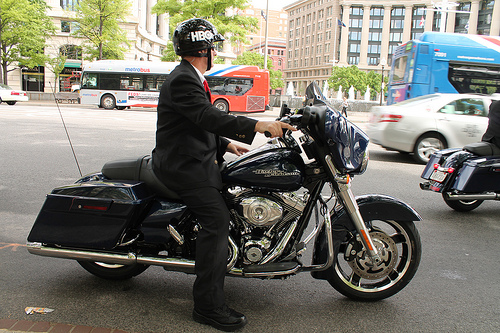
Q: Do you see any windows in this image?
A: Yes, there are windows.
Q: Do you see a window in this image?
A: Yes, there are windows.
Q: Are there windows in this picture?
A: Yes, there are windows.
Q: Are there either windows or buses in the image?
A: Yes, there are windows.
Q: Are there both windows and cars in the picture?
A: Yes, there are both windows and a car.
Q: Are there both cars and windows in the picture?
A: Yes, there are both windows and a car.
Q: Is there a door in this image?
A: No, there are no doors.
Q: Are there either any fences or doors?
A: No, there are no doors or fences.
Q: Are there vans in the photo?
A: No, there are no vans.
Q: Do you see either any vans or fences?
A: No, there are no vans or fences.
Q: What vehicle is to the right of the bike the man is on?
A: The vehicle is a car.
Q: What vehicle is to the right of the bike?
A: The vehicle is a car.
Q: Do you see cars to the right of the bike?
A: Yes, there is a car to the right of the bike.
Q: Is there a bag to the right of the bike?
A: No, there is a car to the right of the bike.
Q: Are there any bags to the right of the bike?
A: No, there is a car to the right of the bike.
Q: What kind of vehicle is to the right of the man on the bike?
A: The vehicle is a car.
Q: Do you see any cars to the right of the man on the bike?
A: Yes, there is a car to the right of the man.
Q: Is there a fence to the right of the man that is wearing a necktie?
A: No, there is a car to the right of the man.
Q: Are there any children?
A: No, there are no children.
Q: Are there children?
A: No, there are no children.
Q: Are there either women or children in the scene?
A: No, there are no children or women.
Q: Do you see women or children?
A: No, there are no children or women.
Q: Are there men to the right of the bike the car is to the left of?
A: Yes, there is a man to the right of the bike.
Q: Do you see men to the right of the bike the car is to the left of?
A: Yes, there is a man to the right of the bike.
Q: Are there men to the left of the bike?
A: No, the man is to the right of the bike.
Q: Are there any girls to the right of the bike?
A: No, there is a man to the right of the bike.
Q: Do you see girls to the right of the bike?
A: No, there is a man to the right of the bike.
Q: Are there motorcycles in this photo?
A: Yes, there is a motorcycle.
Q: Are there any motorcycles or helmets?
A: Yes, there is a motorcycle.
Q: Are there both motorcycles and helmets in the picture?
A: Yes, there are both a motorcycle and a helmet.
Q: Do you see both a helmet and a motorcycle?
A: Yes, there are both a motorcycle and a helmet.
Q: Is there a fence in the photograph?
A: No, there are no fences.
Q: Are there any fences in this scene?
A: No, there are no fences.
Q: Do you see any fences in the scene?
A: No, there are no fences.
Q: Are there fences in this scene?
A: No, there are no fences.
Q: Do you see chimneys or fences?
A: No, there are no fences or chimneys.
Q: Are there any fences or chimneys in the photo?
A: No, there are no fences or chimneys.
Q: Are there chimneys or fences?
A: No, there are no fences or chimneys.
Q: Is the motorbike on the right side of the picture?
A: Yes, the motorbike is on the right of the image.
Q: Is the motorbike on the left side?
A: No, the motorbike is on the right of the image.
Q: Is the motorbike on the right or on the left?
A: The motorbike is on the right of the image.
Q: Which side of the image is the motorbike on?
A: The motorbike is on the right of the image.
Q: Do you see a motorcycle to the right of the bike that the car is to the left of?
A: Yes, there is a motorcycle to the right of the bike.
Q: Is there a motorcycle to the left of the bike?
A: No, the motorcycle is to the right of the bike.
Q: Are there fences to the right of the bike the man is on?
A: No, there is a motorcycle to the right of the bike.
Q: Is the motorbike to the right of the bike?
A: Yes, the motorbike is to the right of the bike.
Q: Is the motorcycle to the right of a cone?
A: No, the motorcycle is to the right of the bike.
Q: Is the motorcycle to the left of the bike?
A: No, the motorcycle is to the right of the bike.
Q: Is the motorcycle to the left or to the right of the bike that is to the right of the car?
A: The motorcycle is to the right of the bike.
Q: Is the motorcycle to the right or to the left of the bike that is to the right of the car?
A: The motorcycle is to the right of the bike.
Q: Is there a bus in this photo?
A: Yes, there is a bus.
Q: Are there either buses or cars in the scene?
A: Yes, there is a bus.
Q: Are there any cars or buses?
A: Yes, there is a bus.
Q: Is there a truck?
A: No, there are no trucks.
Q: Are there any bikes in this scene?
A: Yes, there is a bike.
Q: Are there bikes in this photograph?
A: Yes, there is a bike.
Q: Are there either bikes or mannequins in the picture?
A: Yes, there is a bike.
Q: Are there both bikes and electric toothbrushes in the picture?
A: No, there is a bike but no electric toothbrushes.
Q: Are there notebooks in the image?
A: No, there are no notebooks.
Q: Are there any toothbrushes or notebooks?
A: No, there are no notebooks or toothbrushes.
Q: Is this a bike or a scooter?
A: This is a bike.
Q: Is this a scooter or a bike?
A: This is a bike.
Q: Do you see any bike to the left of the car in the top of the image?
A: No, the bike is to the right of the car.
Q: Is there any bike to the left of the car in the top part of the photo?
A: No, the bike is to the right of the car.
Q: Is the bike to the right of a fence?
A: No, the bike is to the right of the car.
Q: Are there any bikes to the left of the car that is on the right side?
A: Yes, there is a bike to the left of the car.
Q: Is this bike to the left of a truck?
A: No, the bike is to the left of the car.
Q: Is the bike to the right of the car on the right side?
A: No, the bike is to the left of the car.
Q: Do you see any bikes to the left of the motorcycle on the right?
A: Yes, there is a bike to the left of the motorbike.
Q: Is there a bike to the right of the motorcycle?
A: No, the bike is to the left of the motorcycle.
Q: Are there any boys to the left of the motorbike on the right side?
A: No, there is a bike to the left of the motorbike.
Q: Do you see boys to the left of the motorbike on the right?
A: No, there is a bike to the left of the motorbike.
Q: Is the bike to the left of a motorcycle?
A: Yes, the bike is to the left of a motorcycle.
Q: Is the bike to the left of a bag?
A: No, the bike is to the left of a motorcycle.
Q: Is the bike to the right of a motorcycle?
A: No, the bike is to the left of a motorcycle.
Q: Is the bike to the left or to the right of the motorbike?
A: The bike is to the left of the motorbike.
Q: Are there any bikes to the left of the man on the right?
A: Yes, there is a bike to the left of the man.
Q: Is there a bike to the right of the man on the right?
A: No, the bike is to the left of the man.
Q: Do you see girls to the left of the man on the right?
A: No, there is a bike to the left of the man.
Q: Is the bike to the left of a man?
A: Yes, the bike is to the left of a man.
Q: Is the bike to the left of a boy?
A: No, the bike is to the left of a man.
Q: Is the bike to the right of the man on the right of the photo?
A: No, the bike is to the left of the man.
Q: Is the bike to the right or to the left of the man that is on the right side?
A: The bike is to the left of the man.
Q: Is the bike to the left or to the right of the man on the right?
A: The bike is to the left of the man.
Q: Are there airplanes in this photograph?
A: No, there are no airplanes.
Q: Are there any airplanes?
A: No, there are no airplanes.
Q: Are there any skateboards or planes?
A: No, there are no planes or skateboards.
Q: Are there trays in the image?
A: No, there are no trays.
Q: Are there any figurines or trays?
A: No, there are no trays or figurines.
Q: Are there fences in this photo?
A: No, there are no fences.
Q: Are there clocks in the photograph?
A: No, there are no clocks.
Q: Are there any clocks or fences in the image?
A: No, there are no clocks or fences.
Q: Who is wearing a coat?
A: The man is wearing a coat.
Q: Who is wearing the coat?
A: The man is wearing a coat.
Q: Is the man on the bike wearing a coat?
A: Yes, the man is wearing a coat.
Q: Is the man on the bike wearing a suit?
A: No, the man is wearing a coat.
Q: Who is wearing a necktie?
A: The man is wearing a necktie.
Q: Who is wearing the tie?
A: The man is wearing a necktie.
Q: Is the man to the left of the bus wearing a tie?
A: Yes, the man is wearing a tie.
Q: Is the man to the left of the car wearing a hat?
A: No, the man is wearing a tie.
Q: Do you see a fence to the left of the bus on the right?
A: No, there is a man to the left of the bus.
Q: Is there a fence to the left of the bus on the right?
A: No, there is a man to the left of the bus.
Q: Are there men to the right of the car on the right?
A: No, the man is to the left of the car.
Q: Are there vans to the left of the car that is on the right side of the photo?
A: No, there is a man to the left of the car.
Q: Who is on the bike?
A: The man is on the bike.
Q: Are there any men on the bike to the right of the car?
A: Yes, there is a man on the bike.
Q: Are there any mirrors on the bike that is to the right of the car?
A: No, there is a man on the bike.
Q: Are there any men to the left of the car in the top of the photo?
A: No, the man is to the right of the car.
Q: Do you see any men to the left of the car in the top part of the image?
A: No, the man is to the right of the car.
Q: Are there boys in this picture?
A: No, there are no boys.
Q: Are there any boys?
A: No, there are no boys.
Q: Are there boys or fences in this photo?
A: No, there are no boys or fences.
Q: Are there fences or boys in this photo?
A: No, there are no boys or fences.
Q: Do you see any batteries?
A: No, there are no batteries.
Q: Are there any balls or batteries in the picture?
A: No, there are no batteries or balls.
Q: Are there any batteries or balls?
A: No, there are no batteries or balls.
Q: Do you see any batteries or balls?
A: No, there are no batteries or balls.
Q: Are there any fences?
A: No, there are no fences.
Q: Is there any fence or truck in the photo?
A: No, there are no fences or trucks.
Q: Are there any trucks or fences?
A: No, there are no fences or trucks.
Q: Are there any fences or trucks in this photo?
A: No, there are no fences or trucks.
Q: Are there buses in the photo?
A: Yes, there is a bus.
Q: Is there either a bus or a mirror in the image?
A: Yes, there is a bus.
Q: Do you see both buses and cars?
A: Yes, there are both a bus and a car.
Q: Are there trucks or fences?
A: No, there are no fences or trucks.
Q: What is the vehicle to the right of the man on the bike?
A: The vehicle is a bus.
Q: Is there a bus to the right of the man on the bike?
A: Yes, there is a bus to the right of the man.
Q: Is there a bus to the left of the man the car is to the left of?
A: No, the bus is to the right of the man.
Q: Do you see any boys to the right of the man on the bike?
A: No, there is a bus to the right of the man.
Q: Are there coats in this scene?
A: Yes, there is a coat.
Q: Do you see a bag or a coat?
A: Yes, there is a coat.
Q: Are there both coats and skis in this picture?
A: No, there is a coat but no skis.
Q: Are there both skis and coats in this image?
A: No, there is a coat but no skis.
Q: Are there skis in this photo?
A: No, there are no skis.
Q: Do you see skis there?
A: No, there are no skis.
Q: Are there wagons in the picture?
A: No, there are no wagons.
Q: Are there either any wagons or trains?
A: No, there are no wagons or trains.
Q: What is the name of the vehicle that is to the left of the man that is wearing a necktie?
A: The vehicle is a car.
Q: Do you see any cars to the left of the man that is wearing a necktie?
A: Yes, there is a car to the left of the man.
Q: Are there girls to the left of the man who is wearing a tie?
A: No, there is a car to the left of the man.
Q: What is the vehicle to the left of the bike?
A: The vehicle is a car.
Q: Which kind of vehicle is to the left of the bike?
A: The vehicle is a car.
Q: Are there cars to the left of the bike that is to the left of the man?
A: Yes, there is a car to the left of the bike.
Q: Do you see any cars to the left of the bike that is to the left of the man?
A: Yes, there is a car to the left of the bike.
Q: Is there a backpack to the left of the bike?
A: No, there is a car to the left of the bike.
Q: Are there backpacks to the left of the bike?
A: No, there is a car to the left of the bike.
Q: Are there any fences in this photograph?
A: No, there are no fences.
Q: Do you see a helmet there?
A: Yes, there is a helmet.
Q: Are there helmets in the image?
A: Yes, there is a helmet.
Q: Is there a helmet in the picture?
A: Yes, there is a helmet.